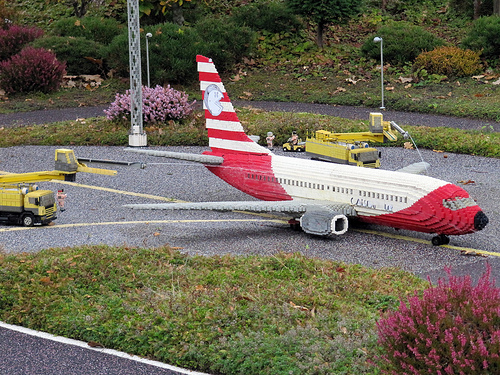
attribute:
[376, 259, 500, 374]
bush — purple, flowering, big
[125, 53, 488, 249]
airplane — red, white, legos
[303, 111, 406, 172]
truck — yellow, small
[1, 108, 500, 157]
grass — green, thick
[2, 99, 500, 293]
concrete — runway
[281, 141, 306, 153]
jeep — small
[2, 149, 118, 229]
truck — small, yellow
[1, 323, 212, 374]
line — white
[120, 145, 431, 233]
wings — grey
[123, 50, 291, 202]
back of plane — red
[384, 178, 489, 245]
front of plane — red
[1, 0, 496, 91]
plant — green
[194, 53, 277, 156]
tail — red, striped, white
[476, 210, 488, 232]
tip — black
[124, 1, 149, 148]
pole — silver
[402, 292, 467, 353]
flowers — violet